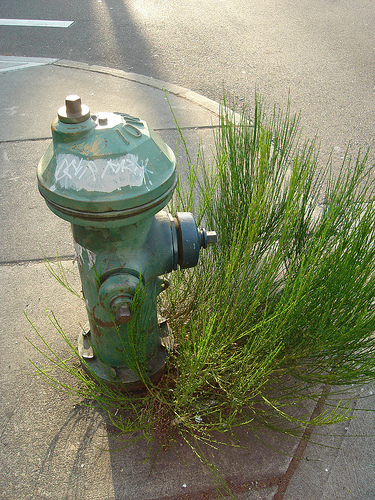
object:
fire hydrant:
[37, 94, 217, 393]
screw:
[206, 231, 217, 244]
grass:
[20, 79, 374, 500]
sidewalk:
[0, 54, 374, 499]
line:
[0, 19, 73, 28]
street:
[0, 1, 375, 237]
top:
[35, 92, 178, 230]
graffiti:
[46, 152, 155, 192]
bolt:
[65, 94, 82, 112]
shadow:
[1, 1, 177, 143]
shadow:
[104, 388, 373, 498]